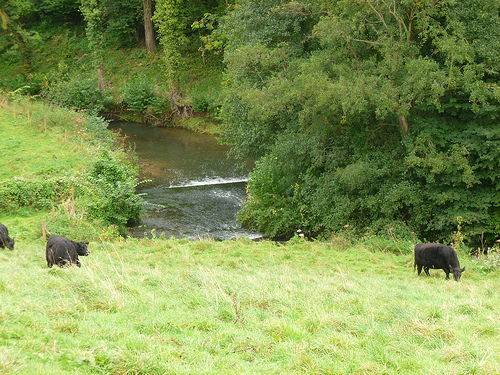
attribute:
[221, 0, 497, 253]
trees — dark green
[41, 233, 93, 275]
cow —  mouth 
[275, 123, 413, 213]
leaves — green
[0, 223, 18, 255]
cow — black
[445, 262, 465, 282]
head — black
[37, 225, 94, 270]
cow — black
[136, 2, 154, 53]
tree — bare, brown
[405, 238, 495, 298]
cow — black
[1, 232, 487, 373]
field — brown , green 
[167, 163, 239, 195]
water — splashing, white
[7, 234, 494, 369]
grass — green 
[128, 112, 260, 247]
water — flowing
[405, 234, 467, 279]
cow — black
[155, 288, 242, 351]
grass — green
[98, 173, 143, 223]
fern — green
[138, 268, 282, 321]
grass — green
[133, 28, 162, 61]
tree trunk — brown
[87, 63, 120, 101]
tree trunk — brown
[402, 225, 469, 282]
cow — black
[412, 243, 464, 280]
cow — black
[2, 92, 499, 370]
grass — brown , green 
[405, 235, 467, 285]
cow — black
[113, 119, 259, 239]
water — calmer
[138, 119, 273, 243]
water — calm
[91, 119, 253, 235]
river — bubbling, small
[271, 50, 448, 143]
forest — green 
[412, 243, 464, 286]
cow — black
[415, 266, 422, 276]
leg — black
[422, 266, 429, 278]
leg — black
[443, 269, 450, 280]
leg — black